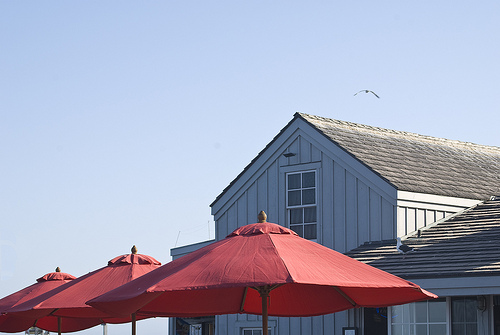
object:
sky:
[1, 4, 498, 281]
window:
[280, 170, 317, 243]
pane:
[288, 174, 300, 188]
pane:
[303, 172, 314, 187]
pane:
[288, 191, 300, 206]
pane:
[302, 189, 315, 206]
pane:
[305, 207, 317, 222]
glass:
[289, 209, 301, 223]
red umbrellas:
[6, 244, 180, 335]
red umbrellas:
[1, 265, 89, 334]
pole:
[129, 312, 136, 334]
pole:
[55, 313, 66, 334]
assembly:
[243, 282, 284, 298]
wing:
[370, 91, 380, 100]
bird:
[349, 86, 379, 100]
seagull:
[396, 237, 415, 260]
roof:
[346, 203, 500, 277]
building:
[208, 112, 500, 335]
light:
[282, 147, 295, 158]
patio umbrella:
[87, 212, 440, 335]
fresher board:
[396, 186, 463, 213]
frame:
[275, 159, 325, 248]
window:
[360, 303, 393, 333]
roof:
[296, 110, 500, 202]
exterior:
[89, 65, 495, 220]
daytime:
[6, 26, 483, 263]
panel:
[82, 235, 231, 303]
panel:
[145, 235, 295, 292]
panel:
[270, 230, 417, 288]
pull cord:
[266, 287, 270, 307]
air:
[3, 3, 337, 136]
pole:
[257, 282, 271, 335]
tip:
[257, 210, 267, 223]